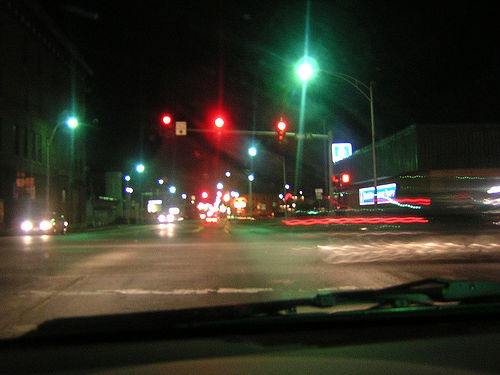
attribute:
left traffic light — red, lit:
[158, 112, 172, 138]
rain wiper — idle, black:
[16, 274, 499, 344]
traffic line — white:
[25, 285, 378, 297]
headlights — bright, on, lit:
[19, 218, 55, 236]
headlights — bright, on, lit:
[157, 212, 177, 226]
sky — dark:
[38, 0, 498, 167]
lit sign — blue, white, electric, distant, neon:
[331, 140, 354, 165]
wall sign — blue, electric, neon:
[358, 180, 400, 207]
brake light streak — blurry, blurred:
[280, 196, 434, 226]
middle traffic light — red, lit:
[213, 116, 226, 142]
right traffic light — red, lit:
[276, 118, 288, 147]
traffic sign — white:
[173, 120, 190, 138]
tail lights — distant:
[203, 216, 219, 225]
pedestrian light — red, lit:
[341, 172, 351, 185]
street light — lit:
[292, 55, 322, 86]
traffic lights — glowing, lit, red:
[159, 113, 291, 147]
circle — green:
[179, 130, 185, 135]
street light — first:
[65, 115, 79, 130]